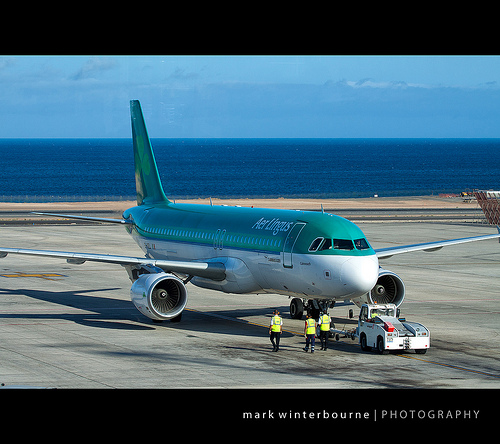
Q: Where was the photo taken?
A: It was taken at the runway.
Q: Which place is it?
A: It is a runway.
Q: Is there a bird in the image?
A: No, there are no birds.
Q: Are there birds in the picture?
A: No, there are no birds.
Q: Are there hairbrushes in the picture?
A: No, there are no hairbrushes.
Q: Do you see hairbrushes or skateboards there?
A: No, there are no hairbrushes or skateboards.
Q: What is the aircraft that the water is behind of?
A: The aircraft is an airplane.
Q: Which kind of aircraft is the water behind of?
A: The water is behind the airplane.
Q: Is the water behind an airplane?
A: Yes, the water is behind an airplane.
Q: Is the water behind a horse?
A: No, the water is behind an airplane.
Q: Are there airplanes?
A: Yes, there is an airplane.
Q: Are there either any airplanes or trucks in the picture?
A: Yes, there is an airplane.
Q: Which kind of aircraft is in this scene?
A: The aircraft is an airplane.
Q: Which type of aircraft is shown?
A: The aircraft is an airplane.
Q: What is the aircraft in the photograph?
A: The aircraft is an airplane.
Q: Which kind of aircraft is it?
A: The aircraft is an airplane.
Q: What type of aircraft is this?
A: That is an airplane.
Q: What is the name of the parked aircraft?
A: The aircraft is an airplane.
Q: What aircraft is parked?
A: The aircraft is an airplane.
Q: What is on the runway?
A: The airplane is on the runway.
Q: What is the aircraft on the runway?
A: The aircraft is an airplane.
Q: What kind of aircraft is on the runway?
A: The aircraft is an airplane.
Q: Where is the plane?
A: The plane is on the runway.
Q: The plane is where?
A: The plane is on the runway.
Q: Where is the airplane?
A: The plane is on the runway.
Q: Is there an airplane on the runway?
A: Yes, there is an airplane on the runway.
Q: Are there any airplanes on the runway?
A: Yes, there is an airplane on the runway.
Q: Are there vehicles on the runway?
A: No, there is an airplane on the runway.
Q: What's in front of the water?
A: The airplane is in front of the water.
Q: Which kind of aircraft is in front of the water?
A: The aircraft is an airplane.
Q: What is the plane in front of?
A: The plane is in front of the water.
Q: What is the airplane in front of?
A: The plane is in front of the water.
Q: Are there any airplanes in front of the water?
A: Yes, there is an airplane in front of the water.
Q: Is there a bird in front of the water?
A: No, there is an airplane in front of the water.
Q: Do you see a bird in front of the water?
A: No, there is an airplane in front of the water.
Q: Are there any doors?
A: Yes, there is a door.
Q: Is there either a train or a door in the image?
A: Yes, there is a door.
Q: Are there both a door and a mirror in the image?
A: No, there is a door but no mirrors.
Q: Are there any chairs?
A: No, there are no chairs.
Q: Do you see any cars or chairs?
A: No, there are no chairs or cars.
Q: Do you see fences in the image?
A: No, there are no fences.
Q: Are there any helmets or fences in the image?
A: No, there are no fences or helmets.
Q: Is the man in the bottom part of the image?
A: Yes, the man is in the bottom of the image.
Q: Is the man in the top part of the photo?
A: No, the man is in the bottom of the image.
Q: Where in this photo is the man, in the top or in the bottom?
A: The man is in the bottom of the image.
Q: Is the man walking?
A: Yes, the man is walking.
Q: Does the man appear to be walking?
A: Yes, the man is walking.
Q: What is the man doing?
A: The man is walking.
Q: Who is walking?
A: The man is walking.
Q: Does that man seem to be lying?
A: No, the man is walking.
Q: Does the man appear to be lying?
A: No, the man is walking.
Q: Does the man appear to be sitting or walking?
A: The man is walking.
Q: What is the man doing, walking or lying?
A: The man is walking.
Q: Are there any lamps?
A: No, there are no lamps.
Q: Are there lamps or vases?
A: No, there are no lamps or vases.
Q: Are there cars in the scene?
A: No, there are no cars.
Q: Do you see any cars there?
A: No, there are no cars.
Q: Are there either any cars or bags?
A: No, there are no cars or bags.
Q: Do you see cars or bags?
A: No, there are no cars or bags.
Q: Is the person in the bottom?
A: Yes, the person is in the bottom of the image.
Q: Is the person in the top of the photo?
A: No, the person is in the bottom of the image.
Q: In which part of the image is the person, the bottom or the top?
A: The person is in the bottom of the image.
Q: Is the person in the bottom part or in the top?
A: The person is in the bottom of the image.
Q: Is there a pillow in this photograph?
A: No, there are no pillows.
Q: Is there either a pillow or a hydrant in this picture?
A: No, there are no pillows or fire hydrants.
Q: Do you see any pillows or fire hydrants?
A: No, there are no pillows or fire hydrants.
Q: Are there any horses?
A: No, there are no horses.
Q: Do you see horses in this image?
A: No, there are no horses.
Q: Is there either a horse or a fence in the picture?
A: No, there are no horses or fences.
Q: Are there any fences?
A: No, there are no fences.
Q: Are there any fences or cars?
A: No, there are no fences or cars.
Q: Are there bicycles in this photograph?
A: No, there are no bicycles.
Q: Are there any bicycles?
A: No, there are no bicycles.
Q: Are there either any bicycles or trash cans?
A: No, there are no bicycles or trash cans.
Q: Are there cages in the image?
A: No, there are no cages.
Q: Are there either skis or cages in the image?
A: No, there are no cages or skis.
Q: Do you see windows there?
A: Yes, there are windows.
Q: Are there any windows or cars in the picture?
A: Yes, there are windows.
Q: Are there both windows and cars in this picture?
A: No, there are windows but no cars.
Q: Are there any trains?
A: No, there are no trains.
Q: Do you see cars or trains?
A: No, there are no trains or cars.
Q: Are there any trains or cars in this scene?
A: No, there are no trains or cars.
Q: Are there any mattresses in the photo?
A: No, there are no mattresses.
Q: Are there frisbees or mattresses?
A: No, there are no mattresses or frisbees.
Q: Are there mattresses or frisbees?
A: No, there are no mattresses or frisbees.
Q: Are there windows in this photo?
A: Yes, there are windows.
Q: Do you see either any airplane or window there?
A: Yes, there are windows.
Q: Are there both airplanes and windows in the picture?
A: Yes, there are both windows and an airplane.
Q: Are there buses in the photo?
A: No, there are no buses.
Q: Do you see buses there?
A: No, there are no buses.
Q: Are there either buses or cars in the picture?
A: No, there are no buses or cars.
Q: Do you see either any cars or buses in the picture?
A: No, there are no buses or cars.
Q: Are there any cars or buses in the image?
A: No, there are no buses or cars.